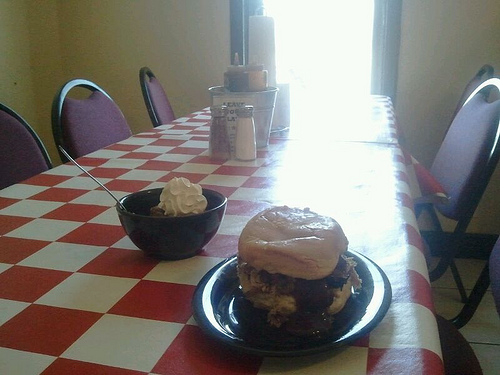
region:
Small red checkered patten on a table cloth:
[5, 291, 110, 366]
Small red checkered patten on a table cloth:
[120, 273, 185, 325]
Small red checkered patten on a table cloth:
[82, 228, 147, 283]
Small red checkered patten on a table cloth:
[58, 218, 125, 255]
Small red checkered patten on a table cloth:
[42, 206, 117, 230]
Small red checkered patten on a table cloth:
[28, 189, 89, 203]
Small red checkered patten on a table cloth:
[21, 168, 88, 185]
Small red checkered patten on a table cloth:
[63, 151, 107, 166]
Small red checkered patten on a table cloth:
[83, 173, 155, 194]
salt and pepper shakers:
[186, 88, 293, 182]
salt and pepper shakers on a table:
[196, 93, 294, 161]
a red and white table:
[18, 234, 131, 332]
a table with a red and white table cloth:
[293, 128, 459, 372]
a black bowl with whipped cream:
[68, 138, 251, 280]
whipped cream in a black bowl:
[76, 148, 221, 271]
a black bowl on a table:
[51, 138, 225, 268]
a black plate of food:
[172, 182, 376, 371]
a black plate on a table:
[164, 213, 414, 372]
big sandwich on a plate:
[168, 203, 408, 359]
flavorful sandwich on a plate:
[161, 199, 404, 359]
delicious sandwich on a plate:
[187, 192, 402, 369]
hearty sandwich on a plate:
[178, 199, 407, 361]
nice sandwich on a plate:
[173, 195, 415, 362]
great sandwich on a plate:
[172, 199, 408, 366]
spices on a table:
[190, 98, 264, 169]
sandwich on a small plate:
[205, 204, 394, 352]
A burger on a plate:
[189, 200, 395, 361]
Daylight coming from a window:
[260, 0, 375, 95]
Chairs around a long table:
[0, 60, 495, 370]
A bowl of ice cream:
[110, 175, 225, 260]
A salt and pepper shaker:
[200, 95, 260, 160]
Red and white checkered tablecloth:
[0, 90, 445, 370]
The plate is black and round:
[186, 240, 386, 356]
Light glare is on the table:
[265, 86, 410, 261]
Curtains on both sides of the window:
[225, 0, 400, 105]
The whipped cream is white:
[155, 171, 210, 216]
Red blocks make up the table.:
[0, 245, 88, 359]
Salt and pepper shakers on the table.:
[197, 93, 266, 171]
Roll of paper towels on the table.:
[243, 10, 282, 90]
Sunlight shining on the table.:
[272, 100, 391, 203]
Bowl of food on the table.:
[115, 168, 234, 255]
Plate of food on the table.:
[196, 191, 386, 358]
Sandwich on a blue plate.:
[191, 202, 388, 362]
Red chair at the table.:
[54, 79, 136, 161]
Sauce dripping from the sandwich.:
[276, 248, 355, 345]